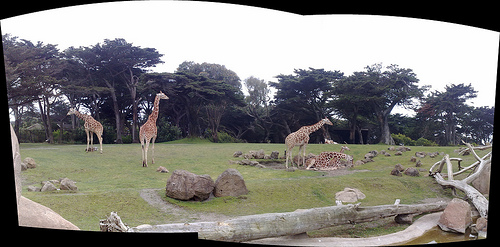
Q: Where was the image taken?
A: It was taken at the field.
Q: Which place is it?
A: It is a field.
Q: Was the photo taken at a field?
A: Yes, it was taken in a field.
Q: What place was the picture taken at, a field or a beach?
A: It was taken at a field.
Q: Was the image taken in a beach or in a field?
A: It was taken at a field.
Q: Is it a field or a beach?
A: It is a field.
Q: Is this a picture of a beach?
A: No, the picture is showing a field.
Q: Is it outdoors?
A: Yes, it is outdoors.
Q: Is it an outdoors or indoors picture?
A: It is outdoors.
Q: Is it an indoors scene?
A: No, it is outdoors.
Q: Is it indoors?
A: No, it is outdoors.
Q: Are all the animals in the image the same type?
A: Yes, all the animals are giraffes.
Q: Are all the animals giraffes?
A: Yes, all the animals are giraffes.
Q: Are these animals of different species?
A: No, all the animals are giraffes.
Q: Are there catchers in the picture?
A: No, there are no catchers.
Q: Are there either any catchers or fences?
A: No, there are no catchers or fences.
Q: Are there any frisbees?
A: No, there are no frisbees.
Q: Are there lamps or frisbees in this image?
A: No, there are no frisbees or lamps.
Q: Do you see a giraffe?
A: Yes, there is a giraffe.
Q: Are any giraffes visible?
A: Yes, there is a giraffe.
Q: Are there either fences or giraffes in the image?
A: Yes, there is a giraffe.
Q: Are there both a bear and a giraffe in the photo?
A: No, there is a giraffe but no bears.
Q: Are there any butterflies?
A: No, there are no butterflies.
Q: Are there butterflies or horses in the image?
A: No, there are no butterflies or horses.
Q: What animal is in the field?
A: The animal is a giraffe.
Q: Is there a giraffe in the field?
A: Yes, there is a giraffe in the field.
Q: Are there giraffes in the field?
A: Yes, there is a giraffe in the field.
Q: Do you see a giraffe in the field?
A: Yes, there is a giraffe in the field.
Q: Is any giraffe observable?
A: Yes, there is a giraffe.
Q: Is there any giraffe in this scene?
A: Yes, there is a giraffe.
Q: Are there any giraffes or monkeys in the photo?
A: Yes, there is a giraffe.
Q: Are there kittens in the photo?
A: No, there are no kittens.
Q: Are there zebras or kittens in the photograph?
A: No, there are no kittens or zebras.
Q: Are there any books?
A: No, there are no books.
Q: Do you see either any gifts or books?
A: No, there are no books or gifts.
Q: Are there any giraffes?
A: Yes, there is a giraffe.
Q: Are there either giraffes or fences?
A: Yes, there is a giraffe.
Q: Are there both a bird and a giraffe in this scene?
A: No, there is a giraffe but no birds.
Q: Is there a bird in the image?
A: No, there are no birds.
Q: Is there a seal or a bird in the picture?
A: No, there are no birds or seals.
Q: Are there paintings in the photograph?
A: No, there are no paintings.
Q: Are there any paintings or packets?
A: No, there are no paintings or packets.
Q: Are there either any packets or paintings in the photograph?
A: No, there are no paintings or packets.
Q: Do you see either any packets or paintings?
A: No, there are no paintings or packets.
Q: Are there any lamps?
A: No, there are no lamps.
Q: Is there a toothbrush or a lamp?
A: No, there are no lamps or toothbrushes.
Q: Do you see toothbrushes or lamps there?
A: No, there are no lamps or toothbrushes.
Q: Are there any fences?
A: No, there are no fences.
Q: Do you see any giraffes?
A: Yes, there is a giraffe.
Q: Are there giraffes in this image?
A: Yes, there is a giraffe.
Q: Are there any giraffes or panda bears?
A: Yes, there is a giraffe.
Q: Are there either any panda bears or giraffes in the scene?
A: Yes, there is a giraffe.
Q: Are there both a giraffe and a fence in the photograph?
A: No, there is a giraffe but no fences.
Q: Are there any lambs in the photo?
A: No, there are no lambs.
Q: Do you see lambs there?
A: No, there are no lambs.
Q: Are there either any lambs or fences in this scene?
A: No, there are no lambs or fences.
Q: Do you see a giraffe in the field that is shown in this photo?
A: Yes, there is a giraffe in the field.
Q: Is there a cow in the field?
A: No, there is a giraffe in the field.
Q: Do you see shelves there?
A: No, there are no shelves.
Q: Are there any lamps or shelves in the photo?
A: No, there are no shelves or lamps.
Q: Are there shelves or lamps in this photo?
A: No, there are no shelves or lamps.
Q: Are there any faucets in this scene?
A: No, there are no faucets.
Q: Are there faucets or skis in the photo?
A: No, there are no faucets or skis.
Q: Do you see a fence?
A: No, there are no fences.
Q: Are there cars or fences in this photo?
A: No, there are no fences or cars.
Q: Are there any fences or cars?
A: No, there are no fences or cars.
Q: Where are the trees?
A: The trees are in the field.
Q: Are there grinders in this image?
A: No, there are no grinders.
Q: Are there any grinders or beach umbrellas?
A: No, there are no grinders or beach umbrellas.